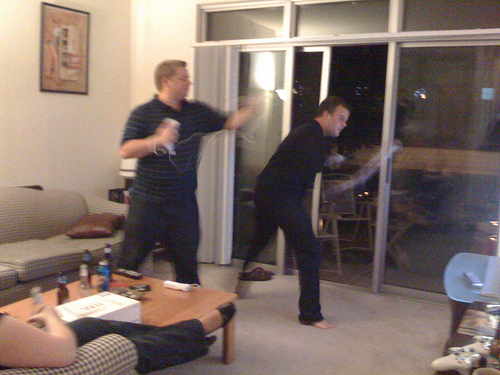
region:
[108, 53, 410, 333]
Two men playing nintendo wii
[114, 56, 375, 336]
two people playing the wii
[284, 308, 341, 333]
the man has no shoes on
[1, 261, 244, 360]
coffee table on the ground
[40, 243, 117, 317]
beer bottles on the coffee table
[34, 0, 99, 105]
picture frame on the wall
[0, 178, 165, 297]
a gray sofa with a brown throw pillow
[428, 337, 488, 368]
game controller on a table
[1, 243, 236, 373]
the woman is sitting on a sofa chair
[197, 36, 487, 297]
sliding glass door out to a patio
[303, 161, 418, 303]
patio furniture outside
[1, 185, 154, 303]
Beige checkered couch with a brown pillow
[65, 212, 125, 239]
brown shiny pillow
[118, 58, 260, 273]
Man in a striped shirt holding a game controller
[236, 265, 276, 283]
Brown shoes sitting on a floor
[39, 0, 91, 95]
Framed picture hanging on a wall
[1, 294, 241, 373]
woman's legs propped up on a coffee table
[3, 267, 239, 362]
Wood coffee table covered in beer bottles, a box and game controllers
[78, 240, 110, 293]
Brown glass beer bottles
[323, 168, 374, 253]
White patio chair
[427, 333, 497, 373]
White game contoller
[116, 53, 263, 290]
Man playing Wii game.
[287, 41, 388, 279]
Open patio door in the background.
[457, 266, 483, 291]
Remote control on table.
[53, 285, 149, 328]
Box on the table.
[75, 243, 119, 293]
Drinks on the tabe.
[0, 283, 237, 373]
Person sitting in the chair.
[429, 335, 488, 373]
xbox game controller on table.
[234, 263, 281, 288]
Sandals by the door.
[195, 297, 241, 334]
back shoe on foot.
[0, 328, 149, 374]
checkered pattern on arm.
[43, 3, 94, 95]
a picture on the wall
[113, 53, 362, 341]
two guys playing a game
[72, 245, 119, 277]
bottles on the table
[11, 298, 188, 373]
someone sitting on the couch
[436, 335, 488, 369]
a game controller paddle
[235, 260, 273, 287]
shoes on the floor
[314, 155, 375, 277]
chairs outside on the patio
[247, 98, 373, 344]
a man wearing a black shirt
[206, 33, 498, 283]
a sliding glass door